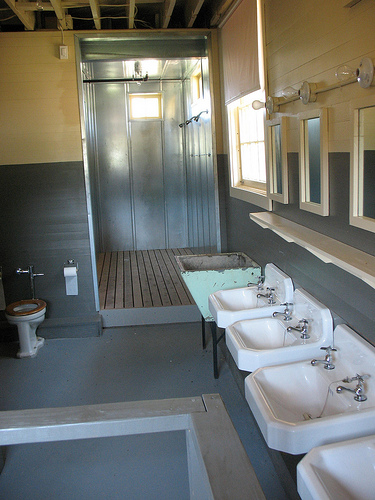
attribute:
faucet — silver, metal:
[330, 372, 361, 402]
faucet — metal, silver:
[308, 340, 337, 372]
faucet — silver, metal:
[286, 316, 316, 343]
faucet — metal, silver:
[269, 300, 294, 323]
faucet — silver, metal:
[255, 286, 277, 303]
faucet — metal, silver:
[242, 274, 269, 292]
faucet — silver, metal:
[246, 272, 267, 293]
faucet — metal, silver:
[273, 301, 296, 322]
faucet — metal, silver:
[287, 319, 312, 341]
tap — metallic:
[328, 372, 363, 404]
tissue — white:
[62, 266, 78, 298]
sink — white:
[204, 260, 294, 335]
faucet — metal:
[270, 299, 293, 324]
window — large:
[223, 85, 272, 213]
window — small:
[125, 92, 165, 122]